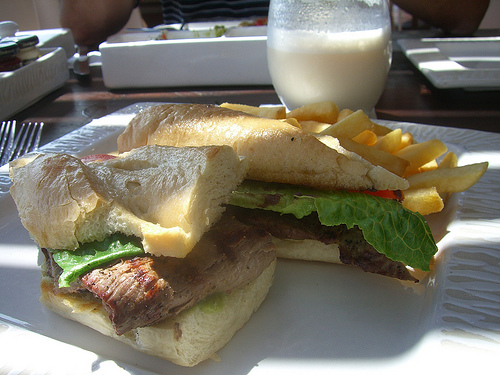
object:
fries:
[401, 186, 445, 216]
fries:
[258, 104, 287, 119]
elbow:
[57, 0, 136, 49]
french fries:
[405, 162, 488, 192]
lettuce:
[45, 233, 149, 285]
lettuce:
[225, 180, 440, 272]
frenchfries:
[397, 138, 448, 170]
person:
[57, 0, 489, 48]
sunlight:
[247, 332, 500, 375]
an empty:
[396, 36, 500, 92]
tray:
[98, 29, 272, 89]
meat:
[39, 215, 277, 337]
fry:
[319, 109, 372, 141]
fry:
[218, 101, 260, 115]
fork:
[0, 120, 42, 165]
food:
[7, 101, 489, 367]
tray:
[397, 37, 500, 92]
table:
[10, 28, 500, 139]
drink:
[269, 28, 394, 119]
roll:
[7, 144, 248, 260]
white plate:
[1, 27, 75, 122]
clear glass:
[265, 0, 389, 121]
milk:
[266, 26, 390, 116]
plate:
[0, 102, 500, 375]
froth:
[266, 26, 381, 38]